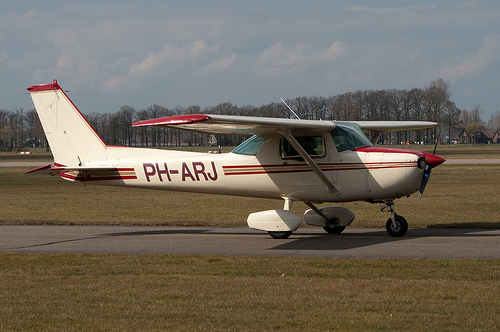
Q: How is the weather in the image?
A: It is cloudy.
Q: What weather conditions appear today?
A: It is cloudy.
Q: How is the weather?
A: It is cloudy.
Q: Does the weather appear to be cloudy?
A: Yes, it is cloudy.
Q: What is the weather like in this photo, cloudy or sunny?
A: It is cloudy.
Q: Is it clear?
A: No, it is cloudy.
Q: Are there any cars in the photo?
A: No, there are no cars.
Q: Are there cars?
A: No, there are no cars.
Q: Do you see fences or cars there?
A: No, there are no cars or fences.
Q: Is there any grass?
A: Yes, there is grass.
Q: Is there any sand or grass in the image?
A: Yes, there is grass.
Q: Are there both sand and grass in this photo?
A: No, there is grass but no sand.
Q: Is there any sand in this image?
A: No, there is no sand.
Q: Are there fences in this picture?
A: No, there are no fences.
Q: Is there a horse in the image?
A: No, there are no horses.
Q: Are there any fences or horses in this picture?
A: No, there are no horses or fences.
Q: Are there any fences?
A: No, there are no fences.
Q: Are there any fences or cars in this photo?
A: No, there are no fences or cars.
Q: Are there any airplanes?
A: Yes, there is an airplane.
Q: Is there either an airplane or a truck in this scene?
A: Yes, there is an airplane.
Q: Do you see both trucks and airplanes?
A: No, there is an airplane but no trucks.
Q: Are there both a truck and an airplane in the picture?
A: No, there is an airplane but no trucks.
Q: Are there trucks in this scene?
A: No, there are no trucks.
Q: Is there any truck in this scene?
A: No, there are no trucks.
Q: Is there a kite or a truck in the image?
A: No, there are no trucks or kites.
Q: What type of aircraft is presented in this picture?
A: The aircraft is an airplane.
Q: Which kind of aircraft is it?
A: The aircraft is an airplane.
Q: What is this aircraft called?
A: That is an airplane.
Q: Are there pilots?
A: No, there are no pilots.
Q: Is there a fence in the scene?
A: No, there are no fences.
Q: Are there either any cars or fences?
A: No, there are no fences or cars.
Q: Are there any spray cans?
A: No, there are no spray cans.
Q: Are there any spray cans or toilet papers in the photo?
A: No, there are no spray cans or toilet papers.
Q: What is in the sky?
A: The clouds are in the sky.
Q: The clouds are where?
A: The clouds are in the sky.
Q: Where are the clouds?
A: The clouds are in the sky.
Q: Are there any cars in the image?
A: No, there are no cars.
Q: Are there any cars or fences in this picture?
A: No, there are no cars or fences.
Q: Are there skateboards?
A: No, there are no skateboards.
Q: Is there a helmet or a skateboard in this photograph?
A: No, there are no skateboards or helmets.